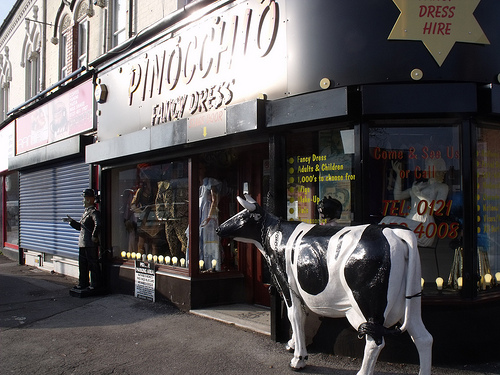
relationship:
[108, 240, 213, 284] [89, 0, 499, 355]
bulbs lining store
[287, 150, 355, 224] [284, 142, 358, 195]
lettering on door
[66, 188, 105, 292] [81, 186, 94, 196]
man in hat